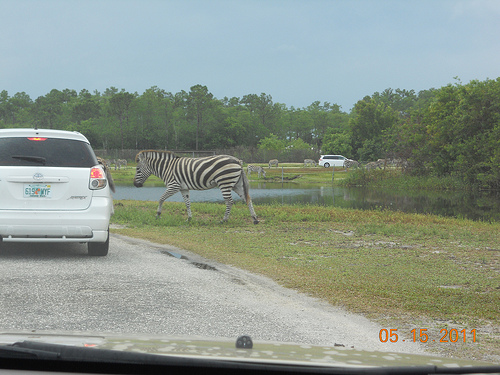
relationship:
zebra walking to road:
[130, 147, 259, 224] [0, 224, 418, 370]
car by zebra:
[0, 127, 113, 256] [133, 150, 262, 228]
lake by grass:
[109, 182, 498, 221] [107, 199, 484, 327]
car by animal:
[318, 155, 354, 169] [300, 156, 317, 168]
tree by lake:
[396, 78, 484, 215] [109, 182, 498, 221]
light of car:
[28, 134, 47, 142] [4, 123, 114, 257]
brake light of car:
[90, 167, 103, 179] [4, 123, 114, 257]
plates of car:
[21, 180, 52, 197] [4, 123, 114, 257]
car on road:
[4, 123, 114, 257] [0, 229, 437, 354]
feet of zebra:
[152, 206, 195, 225] [130, 147, 259, 224]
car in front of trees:
[314, 150, 354, 170] [3, 73, 360, 158]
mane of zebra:
[136, 147, 182, 157] [130, 147, 259, 224]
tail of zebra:
[240, 162, 250, 200] [130, 147, 259, 224]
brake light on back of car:
[90, 167, 103, 179] [4, 123, 114, 257]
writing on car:
[68, 196, 87, 200] [4, 123, 114, 257]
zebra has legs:
[130, 147, 259, 224] [218, 184, 262, 228]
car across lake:
[318, 155, 354, 169] [109, 183, 498, 221]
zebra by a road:
[130, 147, 259, 224] [0, 229, 437, 354]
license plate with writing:
[22, 183, 53, 200] [24, 188, 49, 195]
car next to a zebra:
[0, 127, 113, 256] [132, 141, 262, 227]